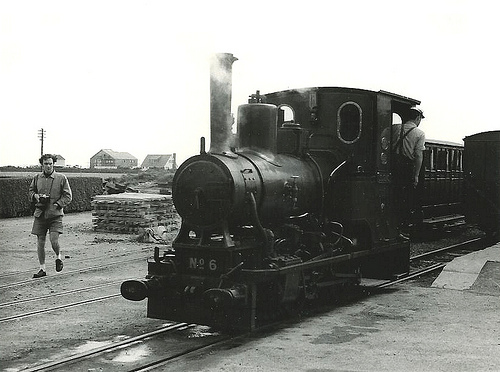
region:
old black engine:
[146, 54, 475, 280]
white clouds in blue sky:
[102, 91, 137, 121]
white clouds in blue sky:
[439, 46, 463, 86]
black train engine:
[167, 88, 477, 320]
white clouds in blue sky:
[266, 39, 334, 90]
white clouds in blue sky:
[22, 43, 60, 71]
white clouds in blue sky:
[87, 69, 159, 120]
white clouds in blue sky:
[106, 58, 188, 120]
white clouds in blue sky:
[135, 103, 153, 118]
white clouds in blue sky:
[431, 55, 479, 112]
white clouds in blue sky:
[111, 73, 156, 108]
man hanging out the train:
[382, 98, 429, 219]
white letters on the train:
[176, 245, 221, 275]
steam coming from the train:
[176, 30, 304, 147]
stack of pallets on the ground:
[86, 183, 179, 249]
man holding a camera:
[36, 185, 55, 215]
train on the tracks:
[149, 64, 424, 313]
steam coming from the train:
[174, 37, 281, 157]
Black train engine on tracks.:
[102, 45, 431, 355]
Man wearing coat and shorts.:
[25, 140, 88, 275]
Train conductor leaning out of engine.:
[360, 57, 428, 289]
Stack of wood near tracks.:
[85, 167, 171, 244]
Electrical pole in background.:
[26, 118, 61, 178]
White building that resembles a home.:
[138, 145, 175, 187]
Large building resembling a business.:
[76, 137, 139, 177]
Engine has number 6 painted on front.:
[131, 147, 257, 334]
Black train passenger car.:
[368, 92, 478, 250]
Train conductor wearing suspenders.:
[388, 93, 439, 219]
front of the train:
[86, 128, 307, 314]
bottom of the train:
[186, 218, 422, 323]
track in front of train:
[92, 307, 211, 369]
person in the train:
[374, 105, 436, 183]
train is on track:
[117, 51, 497, 335]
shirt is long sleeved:
[29, 169, 71, 216]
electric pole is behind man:
[36, 127, 48, 154]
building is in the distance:
[89, 147, 139, 169]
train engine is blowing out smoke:
[206, 48, 238, 150]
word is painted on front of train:
[184, 254, 221, 270]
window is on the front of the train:
[336, 99, 360, 141]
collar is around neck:
[39, 169, 57, 178]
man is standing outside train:
[392, 106, 428, 236]